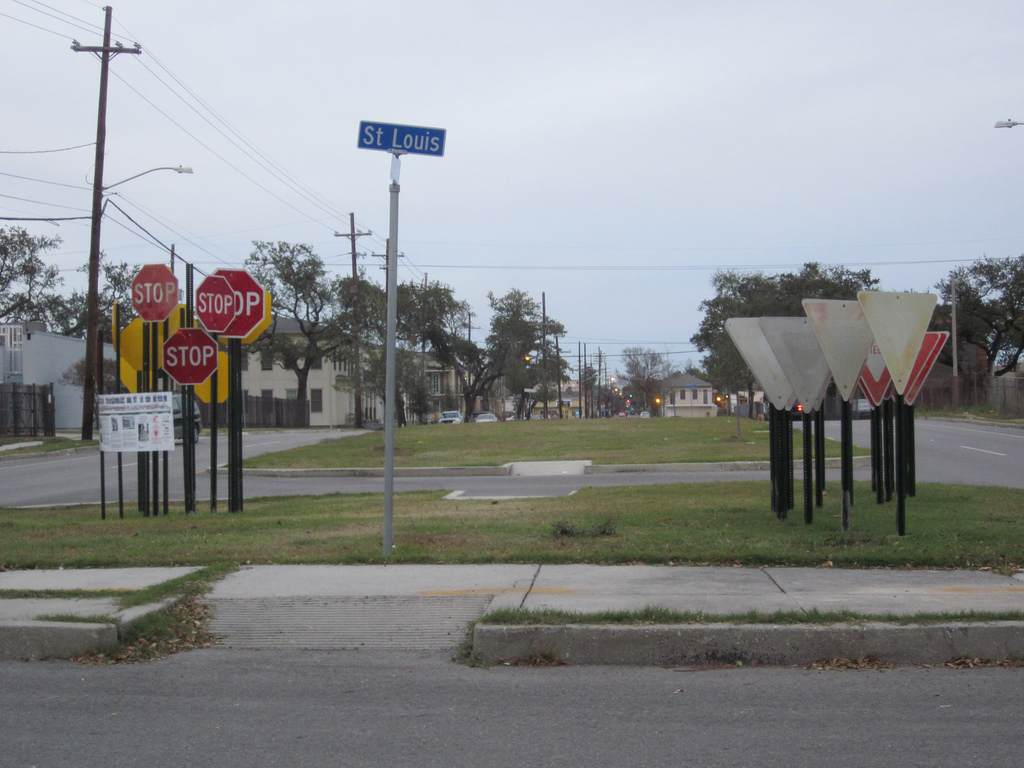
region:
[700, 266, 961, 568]
group of signs on the lawn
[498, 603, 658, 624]
grass on the sidewalk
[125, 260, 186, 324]
stop sign on a pole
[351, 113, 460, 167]
st louis sign on a pole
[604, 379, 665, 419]
traffic lights across the lawn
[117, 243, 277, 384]
group of stop signs on the lawn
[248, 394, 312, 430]
wooden fence near the tree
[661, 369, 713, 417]
house surrounding by traffic lights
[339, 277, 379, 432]
tree near the house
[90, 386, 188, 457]
A white sign on a pole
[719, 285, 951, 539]
A group of white and red triangular signs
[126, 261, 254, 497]
Four red stop signs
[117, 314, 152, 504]
A yellow sign on a pole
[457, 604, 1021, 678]
A curb with grass growing on top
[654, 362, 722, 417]
A cream-colored house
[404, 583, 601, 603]
An orange line on a sidewalk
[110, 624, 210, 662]
A pile of leaves in a gutter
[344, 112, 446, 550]
A tall blue street sign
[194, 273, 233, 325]
the stop sign is red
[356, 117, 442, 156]
the street sign is blue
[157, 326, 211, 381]
the stop sign is red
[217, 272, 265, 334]
the stop sign is red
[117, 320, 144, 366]
the sign is the color yellow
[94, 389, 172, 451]
the poster is white with different color letters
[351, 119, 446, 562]
the street sign is on a pole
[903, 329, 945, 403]
the signs are red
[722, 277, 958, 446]
street signs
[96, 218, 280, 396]
red and white street signs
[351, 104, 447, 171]
blue and white sign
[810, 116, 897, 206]
white clouds in blue sky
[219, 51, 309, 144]
white clouds in blue sky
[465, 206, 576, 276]
white clouds in blue sky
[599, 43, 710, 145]
white clouds in blue sky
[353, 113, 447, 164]
St Louis written on the street sign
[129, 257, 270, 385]
four STOP signs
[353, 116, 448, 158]
a blue and white informational sign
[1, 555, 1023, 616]
a cracked sidewalk filled with grass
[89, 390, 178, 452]
a white and black informational sign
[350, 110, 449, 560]
a metal informational street sign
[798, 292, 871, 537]
a faded yield sign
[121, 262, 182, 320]
a red and white stop sign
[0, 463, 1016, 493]
an asphalt surfaced road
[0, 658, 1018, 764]
an asphalt surfaced road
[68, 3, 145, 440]
a wooden utility pole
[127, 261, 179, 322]
a red stop sign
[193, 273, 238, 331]
a red stop sign